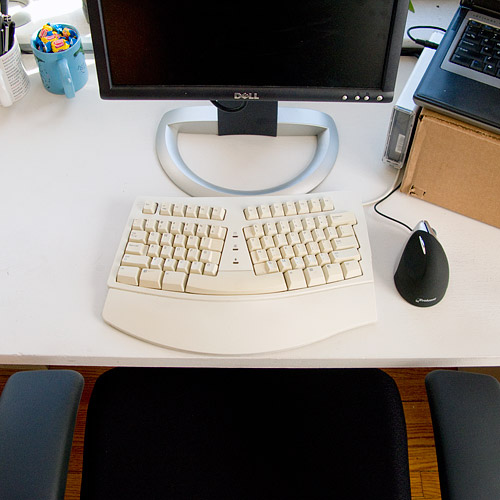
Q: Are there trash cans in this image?
A: No, there are no trash cans.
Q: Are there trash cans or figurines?
A: No, there are no trash cans or figurines.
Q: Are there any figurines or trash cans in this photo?
A: No, there are no trash cans or figurines.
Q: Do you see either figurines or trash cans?
A: No, there are no trash cans or figurines.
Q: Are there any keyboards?
A: Yes, there is a keyboard.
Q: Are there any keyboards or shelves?
A: Yes, there is a keyboard.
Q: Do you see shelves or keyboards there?
A: Yes, there is a keyboard.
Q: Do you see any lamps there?
A: No, there are no lamps.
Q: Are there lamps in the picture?
A: No, there are no lamps.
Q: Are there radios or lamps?
A: No, there are no lamps or radios.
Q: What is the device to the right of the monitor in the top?
A: The device is a keyboard.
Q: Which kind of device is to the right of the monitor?
A: The device is a keyboard.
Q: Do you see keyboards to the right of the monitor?
A: Yes, there is a keyboard to the right of the monitor.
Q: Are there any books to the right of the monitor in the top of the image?
A: No, there is a keyboard to the right of the monitor.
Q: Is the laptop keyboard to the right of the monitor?
A: Yes, the keyboard is to the right of the monitor.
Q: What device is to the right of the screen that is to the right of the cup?
A: The device is a keyboard.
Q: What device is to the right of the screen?
A: The device is a keyboard.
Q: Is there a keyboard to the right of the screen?
A: Yes, there is a keyboard to the right of the screen.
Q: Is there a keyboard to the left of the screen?
A: No, the keyboard is to the right of the screen.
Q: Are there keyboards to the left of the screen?
A: No, the keyboard is to the right of the screen.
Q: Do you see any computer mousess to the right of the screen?
A: No, there is a keyboard to the right of the screen.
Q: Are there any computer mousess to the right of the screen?
A: No, there is a keyboard to the right of the screen.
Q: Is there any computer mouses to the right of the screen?
A: No, there is a keyboard to the right of the screen.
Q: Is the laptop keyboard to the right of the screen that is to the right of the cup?
A: Yes, the keyboard is to the right of the screen.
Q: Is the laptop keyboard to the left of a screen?
A: No, the keyboard is to the right of a screen.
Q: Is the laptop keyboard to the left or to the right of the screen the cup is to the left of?
A: The keyboard is to the right of the screen.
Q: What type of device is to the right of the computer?
A: The device is a keyboard.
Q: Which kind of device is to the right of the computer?
A: The device is a keyboard.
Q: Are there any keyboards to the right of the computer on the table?
A: Yes, there is a keyboard to the right of the computer.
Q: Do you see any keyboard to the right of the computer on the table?
A: Yes, there is a keyboard to the right of the computer.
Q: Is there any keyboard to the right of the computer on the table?
A: Yes, there is a keyboard to the right of the computer.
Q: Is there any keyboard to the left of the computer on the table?
A: No, the keyboard is to the right of the computer.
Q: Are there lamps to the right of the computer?
A: No, there is a keyboard to the right of the computer.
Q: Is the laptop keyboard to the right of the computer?
A: Yes, the keyboard is to the right of the computer.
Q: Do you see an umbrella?
A: No, there are no umbrellas.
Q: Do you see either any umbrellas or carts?
A: No, there are no umbrellas or carts.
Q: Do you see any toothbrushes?
A: No, there are no toothbrushes.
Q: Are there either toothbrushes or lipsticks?
A: No, there are no toothbrushes or lipsticks.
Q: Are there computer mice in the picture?
A: Yes, there is a computer mouse.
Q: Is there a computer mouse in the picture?
A: Yes, there is a computer mouse.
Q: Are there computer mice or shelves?
A: Yes, there is a computer mouse.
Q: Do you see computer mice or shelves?
A: Yes, there is a computer mouse.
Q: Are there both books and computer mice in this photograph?
A: No, there is a computer mouse but no books.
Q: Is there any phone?
A: No, there are no phones.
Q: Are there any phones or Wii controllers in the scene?
A: No, there are no phones or Wii controllers.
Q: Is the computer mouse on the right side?
A: Yes, the computer mouse is on the right of the image.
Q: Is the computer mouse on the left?
A: No, the computer mouse is on the right of the image.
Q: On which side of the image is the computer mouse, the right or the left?
A: The computer mouse is on the right of the image.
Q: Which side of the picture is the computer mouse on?
A: The computer mouse is on the right of the image.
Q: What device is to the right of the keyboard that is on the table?
A: The device is a computer mouse.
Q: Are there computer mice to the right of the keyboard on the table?
A: Yes, there is a computer mouse to the right of the keyboard.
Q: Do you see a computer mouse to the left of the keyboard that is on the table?
A: No, the computer mouse is to the right of the keyboard.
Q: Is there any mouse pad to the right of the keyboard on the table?
A: No, there is a computer mouse to the right of the keyboard.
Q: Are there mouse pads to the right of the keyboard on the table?
A: No, there is a computer mouse to the right of the keyboard.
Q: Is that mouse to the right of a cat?
A: No, the mouse is to the right of the keyboard.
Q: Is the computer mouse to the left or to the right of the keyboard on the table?
A: The computer mouse is to the right of the keyboard.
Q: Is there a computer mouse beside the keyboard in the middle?
A: Yes, there is a computer mouse beside the keyboard.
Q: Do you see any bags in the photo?
A: No, there are no bags.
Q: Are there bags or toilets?
A: No, there are no bags or toilets.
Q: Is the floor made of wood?
A: Yes, the floor is made of wood.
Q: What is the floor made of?
A: The floor is made of wood.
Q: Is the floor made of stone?
A: No, the floor is made of wood.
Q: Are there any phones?
A: No, there are no phones.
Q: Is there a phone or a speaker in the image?
A: No, there are no phones or speakers.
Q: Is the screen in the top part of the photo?
A: Yes, the screen is in the top of the image.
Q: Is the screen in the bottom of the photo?
A: No, the screen is in the top of the image.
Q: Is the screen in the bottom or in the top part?
A: The screen is in the top of the image.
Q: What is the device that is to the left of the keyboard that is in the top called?
A: The device is a screen.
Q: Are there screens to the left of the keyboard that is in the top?
A: Yes, there is a screen to the left of the keyboard.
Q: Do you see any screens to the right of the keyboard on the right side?
A: No, the screen is to the left of the keyboard.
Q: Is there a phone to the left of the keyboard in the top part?
A: No, there is a screen to the left of the keyboard.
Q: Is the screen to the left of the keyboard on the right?
A: Yes, the screen is to the left of the keyboard.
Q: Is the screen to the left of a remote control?
A: No, the screen is to the left of the keyboard.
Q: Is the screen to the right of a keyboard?
A: No, the screen is to the left of a keyboard.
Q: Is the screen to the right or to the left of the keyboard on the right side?
A: The screen is to the left of the keyboard.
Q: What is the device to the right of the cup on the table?
A: The device is a screen.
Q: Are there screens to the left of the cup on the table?
A: No, the screen is to the right of the cup.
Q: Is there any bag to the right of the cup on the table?
A: No, there is a screen to the right of the cup.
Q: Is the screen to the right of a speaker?
A: No, the screen is to the right of the cup.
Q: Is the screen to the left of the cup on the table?
A: No, the screen is to the right of the cup.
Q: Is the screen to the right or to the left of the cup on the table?
A: The screen is to the right of the cup.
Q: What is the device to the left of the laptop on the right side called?
A: The device is a screen.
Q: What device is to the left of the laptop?
A: The device is a screen.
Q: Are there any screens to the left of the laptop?
A: Yes, there is a screen to the left of the laptop.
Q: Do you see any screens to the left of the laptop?
A: Yes, there is a screen to the left of the laptop.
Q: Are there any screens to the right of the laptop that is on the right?
A: No, the screen is to the left of the laptop.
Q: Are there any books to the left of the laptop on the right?
A: No, there is a screen to the left of the laptop.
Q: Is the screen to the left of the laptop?
A: Yes, the screen is to the left of the laptop.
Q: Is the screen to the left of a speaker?
A: No, the screen is to the left of the laptop.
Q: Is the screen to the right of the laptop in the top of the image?
A: No, the screen is to the left of the laptop computer.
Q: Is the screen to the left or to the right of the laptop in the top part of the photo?
A: The screen is to the left of the laptop.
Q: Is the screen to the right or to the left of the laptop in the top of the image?
A: The screen is to the left of the laptop.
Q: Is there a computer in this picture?
A: Yes, there is a computer.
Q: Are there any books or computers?
A: Yes, there is a computer.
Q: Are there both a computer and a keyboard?
A: Yes, there are both a computer and a keyboard.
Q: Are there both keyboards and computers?
A: Yes, there are both a computer and a keyboard.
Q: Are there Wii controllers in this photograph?
A: No, there are no Wii controllers.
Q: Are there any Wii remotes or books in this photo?
A: No, there are no Wii remotes or books.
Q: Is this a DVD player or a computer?
A: This is a computer.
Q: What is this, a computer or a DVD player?
A: This is a computer.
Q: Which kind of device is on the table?
A: The device is a computer.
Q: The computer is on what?
A: The computer is on the table.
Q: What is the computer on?
A: The computer is on the table.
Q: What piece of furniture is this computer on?
A: The computer is on the table.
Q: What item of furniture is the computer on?
A: The computer is on the table.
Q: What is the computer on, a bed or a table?
A: The computer is on a table.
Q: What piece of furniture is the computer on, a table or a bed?
A: The computer is on a table.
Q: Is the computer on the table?
A: Yes, the computer is on the table.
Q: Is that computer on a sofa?
A: No, the computer is on the table.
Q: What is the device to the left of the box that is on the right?
A: The device is a computer.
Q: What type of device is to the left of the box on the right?
A: The device is a computer.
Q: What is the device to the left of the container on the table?
A: The device is a computer.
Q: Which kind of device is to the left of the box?
A: The device is a computer.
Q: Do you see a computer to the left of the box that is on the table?
A: Yes, there is a computer to the left of the box.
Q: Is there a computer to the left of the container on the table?
A: Yes, there is a computer to the left of the box.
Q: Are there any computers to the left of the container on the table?
A: Yes, there is a computer to the left of the box.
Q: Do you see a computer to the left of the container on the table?
A: Yes, there is a computer to the left of the box.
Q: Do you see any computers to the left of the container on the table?
A: Yes, there is a computer to the left of the box.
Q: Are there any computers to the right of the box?
A: No, the computer is to the left of the box.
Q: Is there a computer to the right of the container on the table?
A: No, the computer is to the left of the box.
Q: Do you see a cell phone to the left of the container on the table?
A: No, there is a computer to the left of the box.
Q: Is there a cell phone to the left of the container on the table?
A: No, there is a computer to the left of the box.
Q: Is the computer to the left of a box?
A: Yes, the computer is to the left of a box.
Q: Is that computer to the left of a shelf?
A: No, the computer is to the left of a box.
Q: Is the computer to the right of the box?
A: No, the computer is to the left of the box.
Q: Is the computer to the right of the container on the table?
A: No, the computer is to the left of the box.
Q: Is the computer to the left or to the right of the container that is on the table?
A: The computer is to the left of the box.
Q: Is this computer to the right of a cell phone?
A: No, the computer is to the right of the cup.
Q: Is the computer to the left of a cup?
A: No, the computer is to the right of a cup.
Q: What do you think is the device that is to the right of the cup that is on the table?
A: The device is a computer.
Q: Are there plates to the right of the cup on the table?
A: No, there is a computer to the right of the cup.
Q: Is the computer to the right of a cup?
A: Yes, the computer is to the right of a cup.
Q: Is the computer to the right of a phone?
A: No, the computer is to the right of a cup.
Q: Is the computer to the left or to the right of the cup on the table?
A: The computer is to the right of the cup.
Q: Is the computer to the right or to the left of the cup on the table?
A: The computer is to the right of the cup.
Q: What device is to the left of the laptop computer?
A: The device is a computer.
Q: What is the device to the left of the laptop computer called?
A: The device is a computer.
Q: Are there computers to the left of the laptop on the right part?
A: Yes, there is a computer to the left of the laptop.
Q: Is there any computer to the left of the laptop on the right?
A: Yes, there is a computer to the left of the laptop.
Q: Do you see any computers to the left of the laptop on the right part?
A: Yes, there is a computer to the left of the laptop.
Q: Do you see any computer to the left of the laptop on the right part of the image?
A: Yes, there is a computer to the left of the laptop.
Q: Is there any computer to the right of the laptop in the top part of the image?
A: No, the computer is to the left of the laptop computer.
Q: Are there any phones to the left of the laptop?
A: No, there is a computer to the left of the laptop.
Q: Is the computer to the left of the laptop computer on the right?
A: Yes, the computer is to the left of the laptop computer.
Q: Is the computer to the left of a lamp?
A: No, the computer is to the left of the laptop computer.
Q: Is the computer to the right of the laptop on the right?
A: No, the computer is to the left of the laptop computer.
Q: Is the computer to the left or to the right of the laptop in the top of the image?
A: The computer is to the left of the laptop.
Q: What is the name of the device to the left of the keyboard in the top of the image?
A: The device is a computer.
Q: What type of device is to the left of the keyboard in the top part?
A: The device is a computer.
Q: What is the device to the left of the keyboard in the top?
A: The device is a computer.